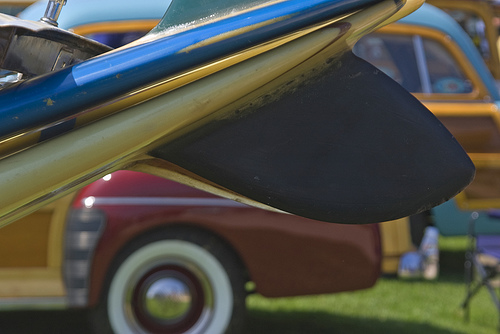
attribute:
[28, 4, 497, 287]
car — shiny, chrome, yellow, blue, metallic, vintage, red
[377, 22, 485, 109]
window frame — yellow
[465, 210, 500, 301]
chair — metal, folding, purple, blue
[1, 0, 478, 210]
surfboard — yellow, blue, silver, chrome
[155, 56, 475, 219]
fin — dark, black, blue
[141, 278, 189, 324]
hubcap — red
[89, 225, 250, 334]
tire — circle, white, silver, black, red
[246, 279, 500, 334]
grass — green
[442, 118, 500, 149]
panel — wood